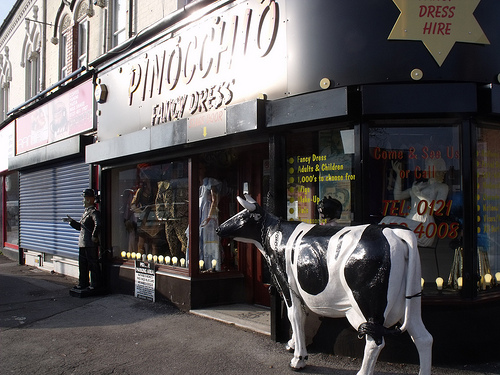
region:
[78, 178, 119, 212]
head of a person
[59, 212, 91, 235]
arm of a person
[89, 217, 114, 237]
arm of a person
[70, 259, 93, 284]
leg of a person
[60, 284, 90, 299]
feet of a person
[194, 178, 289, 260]
head of a cow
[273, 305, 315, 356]
leg of a cow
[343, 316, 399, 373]
leg of a cow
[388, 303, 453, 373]
leg of a cow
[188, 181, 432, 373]
this is a fake cow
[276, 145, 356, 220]
yellow decal on the window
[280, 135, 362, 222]
yellow text on the glass window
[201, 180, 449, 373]
this is a cow statue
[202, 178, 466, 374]
the cow is chained to the wall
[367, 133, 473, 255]
the text decal is red and yellow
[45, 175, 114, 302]
this is a statue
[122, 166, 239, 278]
mannequins in a window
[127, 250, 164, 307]
this is a black and white sign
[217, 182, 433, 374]
fake black and white cow in front of shop window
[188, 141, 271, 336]
shop entryway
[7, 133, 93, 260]
roll up accordian style security door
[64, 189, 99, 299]
carved figure of person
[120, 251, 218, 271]
row of light bulbs in shop window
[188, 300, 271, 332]
tiled shop entryway flooring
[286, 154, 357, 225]
shop information painted on storefront window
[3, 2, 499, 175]
large marquee sign space for ground floor shops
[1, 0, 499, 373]
city building with first floor business space and second floor residential space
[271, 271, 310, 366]
the leg of the cow statue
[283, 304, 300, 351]
the leg of the cow statue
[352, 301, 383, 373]
the leg of the cow statue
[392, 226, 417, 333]
the tail of the cow statue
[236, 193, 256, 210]
the horn of the cow statue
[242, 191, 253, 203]
the horn of the cow statue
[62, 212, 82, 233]
the arm of the mannequin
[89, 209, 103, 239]
the arm of the mannequin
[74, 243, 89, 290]
the leg of the mannequin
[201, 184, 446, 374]
a statue of a cow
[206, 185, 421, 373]
a statue of a cow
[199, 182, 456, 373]
a statue of a cow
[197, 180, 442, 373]
a statue of a cow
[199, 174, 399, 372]
a statue of a cow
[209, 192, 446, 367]
a black and white cow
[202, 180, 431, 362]
a black and white cow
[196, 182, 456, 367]
a black and white cow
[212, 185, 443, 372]
a statue of a black and white cow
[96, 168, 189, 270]
a window on a building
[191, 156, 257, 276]
a window on a building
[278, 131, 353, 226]
a window on a building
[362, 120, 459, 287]
a window on a building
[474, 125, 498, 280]
a window on a building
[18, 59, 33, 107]
a window on a building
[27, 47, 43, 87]
a window on a building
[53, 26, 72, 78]
a window on a building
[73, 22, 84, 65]
a window on a building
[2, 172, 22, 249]
a window on a building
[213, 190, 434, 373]
cow in front of window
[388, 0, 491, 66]
yellow star above store window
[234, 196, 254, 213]
white horn attached to cow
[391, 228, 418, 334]
white tail attached to cow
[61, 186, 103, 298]
statue in front of store window